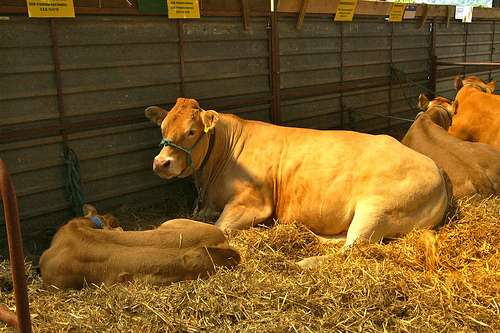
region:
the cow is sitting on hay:
[135, 95, 485, 256]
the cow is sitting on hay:
[358, 80, 499, 255]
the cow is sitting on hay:
[391, 55, 488, 120]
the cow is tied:
[358, 87, 497, 268]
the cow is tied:
[398, 56, 498, 178]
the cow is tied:
[146, 96, 489, 298]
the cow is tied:
[50, 165, 287, 313]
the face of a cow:
[130, 87, 240, 180]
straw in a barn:
[252, 268, 409, 331]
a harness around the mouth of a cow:
[155, 124, 202, 175]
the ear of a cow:
[195, 109, 228, 134]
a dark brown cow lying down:
[47, 199, 240, 299]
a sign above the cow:
[165, 2, 201, 22]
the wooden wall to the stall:
[30, 43, 146, 192]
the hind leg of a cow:
[298, 209, 388, 274]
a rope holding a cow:
[44, 147, 104, 224]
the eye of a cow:
[182, 125, 199, 144]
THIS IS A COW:
[128, 95, 474, 278]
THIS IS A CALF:
[45, 201, 232, 298]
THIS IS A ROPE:
[131, 108, 257, 208]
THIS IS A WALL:
[57, 54, 116, 82]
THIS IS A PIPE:
[4, 151, 28, 331]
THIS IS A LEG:
[289, 205, 417, 278]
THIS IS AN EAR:
[188, 100, 226, 142]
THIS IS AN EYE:
[181, 120, 209, 143]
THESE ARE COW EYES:
[151, 115, 216, 144]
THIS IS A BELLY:
[275, 182, 371, 247]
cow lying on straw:
[131, 88, 453, 277]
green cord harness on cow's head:
[155, 116, 222, 192]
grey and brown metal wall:
[2, 3, 497, 283]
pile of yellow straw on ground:
[3, 195, 498, 332]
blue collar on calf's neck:
[79, 209, 108, 230]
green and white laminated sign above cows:
[22, 0, 82, 23]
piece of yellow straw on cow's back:
[167, 230, 193, 253]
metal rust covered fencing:
[1, 159, 38, 328]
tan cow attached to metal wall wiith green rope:
[345, 93, 499, 200]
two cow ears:
[140, 96, 224, 133]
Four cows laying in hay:
[15, 65, 497, 321]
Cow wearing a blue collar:
[33, 199, 249, 302]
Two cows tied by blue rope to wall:
[310, 60, 498, 140]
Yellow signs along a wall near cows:
[0, 2, 495, 217]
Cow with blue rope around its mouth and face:
[120, 70, 231, 209]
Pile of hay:
[254, 235, 491, 330]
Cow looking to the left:
[108, 82, 255, 192]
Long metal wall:
[36, 21, 488, 86]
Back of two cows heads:
[401, 64, 497, 126]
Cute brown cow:
[120, 84, 229, 199]